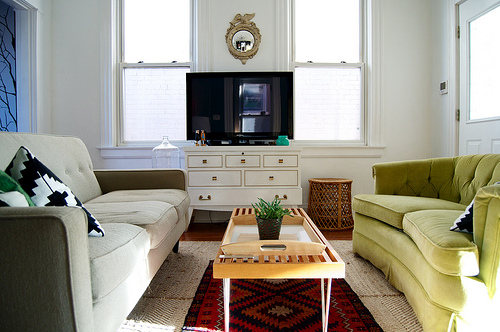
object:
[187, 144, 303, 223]
dresser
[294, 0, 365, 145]
window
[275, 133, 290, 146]
jar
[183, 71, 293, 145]
television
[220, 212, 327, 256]
tray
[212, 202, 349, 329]
coffee table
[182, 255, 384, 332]
rug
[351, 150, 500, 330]
green sofa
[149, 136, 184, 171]
glass jug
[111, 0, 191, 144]
window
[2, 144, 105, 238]
pillows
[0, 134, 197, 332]
sofa